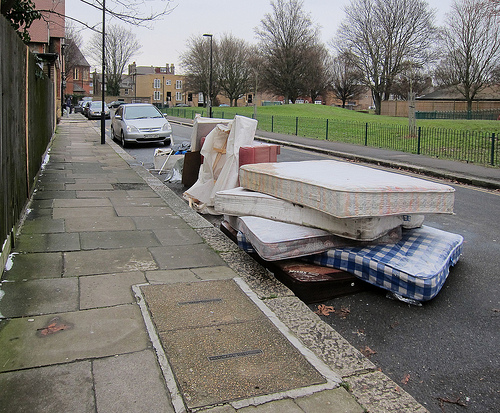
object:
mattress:
[234, 222, 465, 303]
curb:
[336, 332, 429, 411]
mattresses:
[221, 211, 403, 264]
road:
[91, 108, 498, 408]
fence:
[413, 126, 498, 166]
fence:
[440, 98, 499, 118]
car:
[110, 102, 172, 146]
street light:
[202, 32, 214, 115]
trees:
[249, 0, 329, 106]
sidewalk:
[0, 251, 428, 412]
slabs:
[137, 277, 328, 410]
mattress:
[236, 157, 457, 219]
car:
[86, 101, 111, 119]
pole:
[100, 1, 107, 144]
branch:
[25, 7, 110, 38]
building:
[134, 70, 198, 106]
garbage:
[151, 113, 281, 213]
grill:
[140, 126, 162, 137]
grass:
[255, 103, 357, 118]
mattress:
[212, 184, 426, 240]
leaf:
[315, 302, 334, 315]